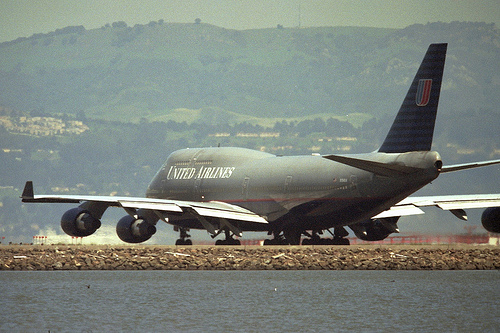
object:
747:
[18, 43, 499, 246]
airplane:
[18, 42, 500, 245]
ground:
[426, 49, 500, 159]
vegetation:
[0, 18, 500, 243]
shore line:
[0, 245, 500, 272]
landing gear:
[173, 225, 349, 245]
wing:
[19, 181, 270, 224]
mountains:
[0, 18, 500, 240]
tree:
[0, 17, 500, 233]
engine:
[61, 208, 103, 238]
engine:
[116, 214, 156, 243]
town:
[0, 116, 87, 136]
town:
[208, 133, 356, 153]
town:
[51, 183, 130, 198]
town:
[446, 143, 498, 154]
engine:
[349, 216, 401, 241]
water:
[0, 268, 500, 333]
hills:
[0, 19, 500, 241]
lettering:
[194, 166, 236, 180]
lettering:
[166, 166, 196, 180]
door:
[240, 176, 249, 202]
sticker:
[167, 166, 235, 181]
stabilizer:
[376, 42, 449, 153]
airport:
[0, 222, 500, 270]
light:
[32, 236, 47, 244]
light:
[72, 237, 83, 245]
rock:
[0, 248, 500, 271]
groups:
[0, 247, 500, 271]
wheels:
[175, 239, 350, 246]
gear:
[60, 208, 155, 244]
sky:
[1, 0, 500, 44]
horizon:
[0, 0, 499, 42]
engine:
[481, 207, 500, 234]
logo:
[415, 78, 432, 106]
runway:
[0, 242, 500, 249]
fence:
[344, 235, 457, 244]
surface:
[0, 244, 500, 333]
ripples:
[0, 270, 500, 333]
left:
[18, 180, 269, 237]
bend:
[19, 180, 45, 203]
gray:
[144, 147, 442, 215]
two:
[59, 207, 157, 244]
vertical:
[377, 43, 449, 154]